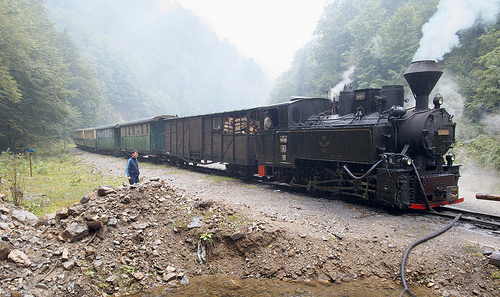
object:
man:
[126, 149, 140, 185]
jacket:
[126, 157, 139, 176]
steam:
[411, 0, 499, 62]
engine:
[259, 60, 464, 214]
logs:
[222, 114, 261, 137]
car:
[164, 102, 337, 183]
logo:
[317, 134, 331, 154]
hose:
[402, 212, 462, 294]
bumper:
[411, 197, 463, 210]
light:
[437, 97, 443, 106]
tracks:
[77, 143, 500, 225]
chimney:
[404, 59, 443, 109]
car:
[120, 115, 171, 159]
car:
[95, 123, 121, 155]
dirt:
[0, 178, 354, 296]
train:
[72, 61, 463, 216]